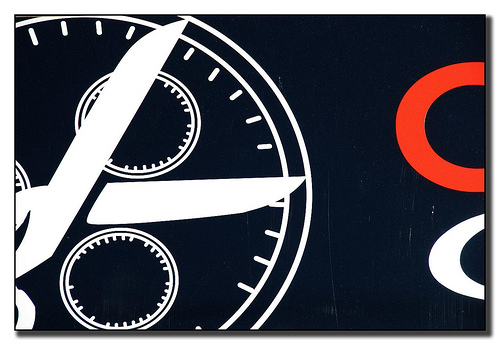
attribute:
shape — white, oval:
[21, 3, 313, 333]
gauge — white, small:
[12, 48, 322, 330]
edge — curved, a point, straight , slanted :
[95, 154, 395, 214]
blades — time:
[61, 26, 316, 236]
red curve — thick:
[385, 54, 485, 195]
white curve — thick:
[426, 211, 483, 306]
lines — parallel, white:
[19, 16, 311, 329]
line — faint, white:
[323, 177, 342, 335]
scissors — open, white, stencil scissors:
[13, 18, 306, 329]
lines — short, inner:
[19, 37, 271, 343]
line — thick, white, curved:
[411, 218, 497, 318]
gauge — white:
[36, 26, 341, 340]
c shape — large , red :
[449, 57, 484, 99]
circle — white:
[45, 228, 212, 343]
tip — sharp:
[269, 170, 349, 231]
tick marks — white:
[46, 233, 196, 338]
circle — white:
[207, 22, 324, 147]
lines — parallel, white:
[193, 101, 203, 126]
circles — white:
[60, 60, 200, 338]